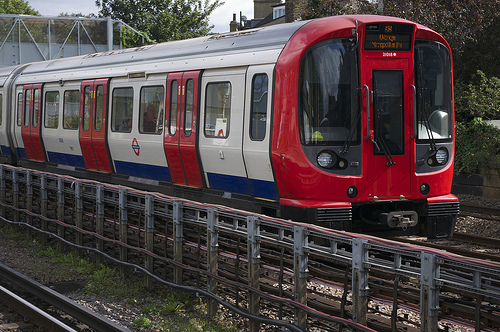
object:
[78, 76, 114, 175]
door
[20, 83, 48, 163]
door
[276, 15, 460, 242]
front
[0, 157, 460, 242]
bottom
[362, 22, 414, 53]
sign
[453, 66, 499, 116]
tree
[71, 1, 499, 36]
back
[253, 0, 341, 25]
building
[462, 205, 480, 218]
part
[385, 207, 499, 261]
track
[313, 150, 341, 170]
headlight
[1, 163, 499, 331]
fence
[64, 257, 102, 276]
grass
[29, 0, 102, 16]
sky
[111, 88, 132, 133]
window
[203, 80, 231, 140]
window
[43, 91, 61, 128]
window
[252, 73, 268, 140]
window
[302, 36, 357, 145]
window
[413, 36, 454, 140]
window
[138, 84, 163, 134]
window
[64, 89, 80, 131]
window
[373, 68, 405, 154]
windshield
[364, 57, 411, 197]
door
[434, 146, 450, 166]
headlight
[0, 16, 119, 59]
barrier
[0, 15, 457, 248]
subway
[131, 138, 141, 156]
logo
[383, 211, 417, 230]
towhook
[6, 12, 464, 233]
train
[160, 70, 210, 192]
door